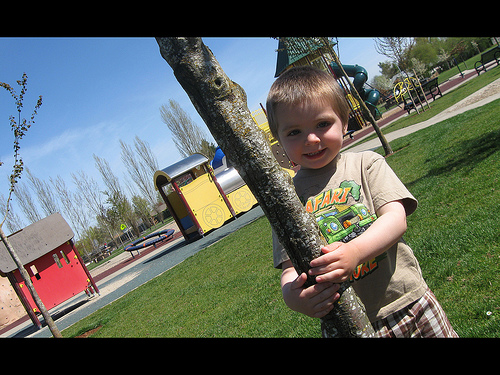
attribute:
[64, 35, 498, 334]
grass — green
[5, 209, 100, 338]
building — red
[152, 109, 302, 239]
train — yellow, play toy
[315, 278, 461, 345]
shorts — plaid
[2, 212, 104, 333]
play house — red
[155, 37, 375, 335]
tree — small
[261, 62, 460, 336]
boy — little, young, smiling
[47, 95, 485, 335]
field — grassy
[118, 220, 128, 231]
sign — black, yellow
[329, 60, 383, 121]
slide — green, enclosed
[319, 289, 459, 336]
shorts — plaid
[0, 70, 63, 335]
tree — small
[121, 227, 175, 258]
trampoline — blue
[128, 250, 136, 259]
leg — short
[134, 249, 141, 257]
leg — short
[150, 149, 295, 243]
train — yellow